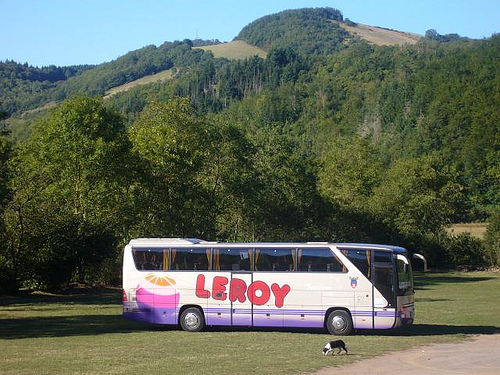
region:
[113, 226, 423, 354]
dog in front of painted bus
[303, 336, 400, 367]
black and white dog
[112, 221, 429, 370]
bus parked on grass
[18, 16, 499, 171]
hill covered with trees and meadows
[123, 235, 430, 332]
bus windows with curtains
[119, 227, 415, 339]
bus with writing on side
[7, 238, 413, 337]
shadow of bus on grass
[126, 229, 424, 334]
bus with wall of windows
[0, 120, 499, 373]
grassy field by trees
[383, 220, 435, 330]
rear view mirrors on front of bus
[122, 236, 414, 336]
the bus parked on the grass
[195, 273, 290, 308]
the word LEROY on the side of the bus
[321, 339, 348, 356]
the dog on the grass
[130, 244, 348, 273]
the passenger windows on the side of the bus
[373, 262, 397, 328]
the door on the bus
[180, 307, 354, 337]
the wheels on the bus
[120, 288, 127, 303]
the red light on the back of the bus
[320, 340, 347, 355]
the white markings on the dog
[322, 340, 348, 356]
the black markings on the dog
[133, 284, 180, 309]
the pink paint on the bus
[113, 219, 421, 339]
A bus in the foreground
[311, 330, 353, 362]
A dog in the foreground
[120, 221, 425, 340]
The bus is white in color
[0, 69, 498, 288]
Tall trees in the background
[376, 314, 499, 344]
Bus is casting a shadow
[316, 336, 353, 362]
Dog's coat is black and white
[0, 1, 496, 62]
The sky is clear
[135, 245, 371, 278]
Busses windows are tinted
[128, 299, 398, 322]
Bus has a purple stripe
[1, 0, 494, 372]
Photo was taken outdoors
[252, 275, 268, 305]
side of a bus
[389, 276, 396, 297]
edge of a bus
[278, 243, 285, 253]
window of a bus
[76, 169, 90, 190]
part of a branch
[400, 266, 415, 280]
part of a window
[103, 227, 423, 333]
a charter bus parked in a field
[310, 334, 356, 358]
a black and white dog standing in a field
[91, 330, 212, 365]
green grass of the field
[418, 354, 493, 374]
brown dirt of the road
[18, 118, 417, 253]
several trees growing behind the bus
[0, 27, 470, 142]
rolling hills in the distance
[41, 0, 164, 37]
clear blue skies over the scene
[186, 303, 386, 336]
purple stripes on the bottom of the bus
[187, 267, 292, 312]
red lettering on the side of the bus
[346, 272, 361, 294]
blue and red logo on the bus